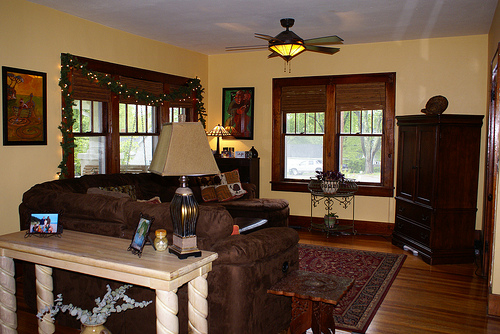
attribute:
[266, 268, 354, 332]
end table — short, wood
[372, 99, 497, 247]
cabinet — large, wooden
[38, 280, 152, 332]
floral arrangment — white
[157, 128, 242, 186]
tan shade — tan 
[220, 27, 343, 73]
fan — five blade, ceiling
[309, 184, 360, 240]
stand — decorative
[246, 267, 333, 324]
side table — brown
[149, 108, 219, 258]
lamp — golden and tan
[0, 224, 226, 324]
table — light wood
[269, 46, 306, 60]
light — on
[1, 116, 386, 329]
sofa — dark brown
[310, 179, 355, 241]
stand — small, iron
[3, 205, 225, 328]
table — light , wood 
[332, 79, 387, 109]
blind — open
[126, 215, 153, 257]
picture — framed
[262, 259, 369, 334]
table — dark brown